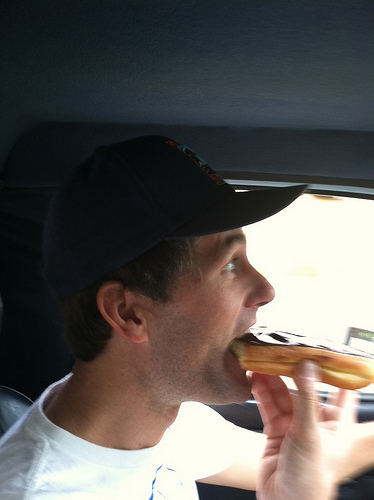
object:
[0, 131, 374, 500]
man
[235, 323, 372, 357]
icing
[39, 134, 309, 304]
hat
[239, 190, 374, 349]
light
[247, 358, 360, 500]
hand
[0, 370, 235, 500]
t-shirt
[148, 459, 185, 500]
design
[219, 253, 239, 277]
eye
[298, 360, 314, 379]
fingernail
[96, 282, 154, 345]
ear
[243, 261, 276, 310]
nose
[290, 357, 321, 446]
thumb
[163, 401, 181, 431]
adam's apple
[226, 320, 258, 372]
mouth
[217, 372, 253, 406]
chin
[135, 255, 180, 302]
sideburns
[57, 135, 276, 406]
head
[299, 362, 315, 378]
thumbnail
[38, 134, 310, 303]
baseball cap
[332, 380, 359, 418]
finger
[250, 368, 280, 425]
finger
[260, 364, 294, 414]
finger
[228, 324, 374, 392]
eclair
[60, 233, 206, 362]
hair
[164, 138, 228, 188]
logo